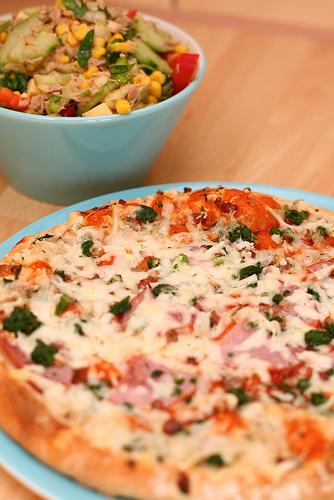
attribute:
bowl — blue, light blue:
[14, 105, 191, 184]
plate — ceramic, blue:
[118, 177, 190, 198]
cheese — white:
[129, 273, 226, 347]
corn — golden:
[51, 19, 89, 49]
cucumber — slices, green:
[2, 17, 57, 60]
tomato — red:
[158, 51, 205, 87]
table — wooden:
[220, 3, 330, 156]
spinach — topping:
[225, 221, 261, 251]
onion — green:
[89, 75, 135, 104]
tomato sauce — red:
[246, 197, 264, 233]